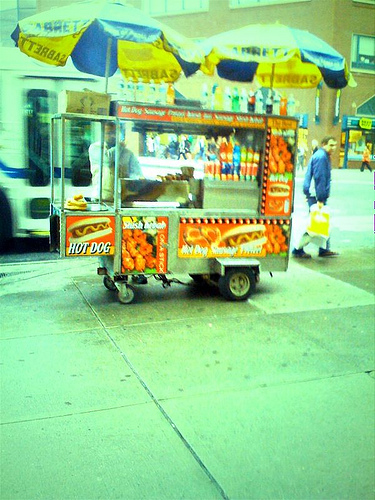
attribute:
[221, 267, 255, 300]
tire — black, small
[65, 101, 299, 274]
hot dog sign — red, yellow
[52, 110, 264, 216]
display — encased in glass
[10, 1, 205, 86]
sabrett umbrella — blue, yellow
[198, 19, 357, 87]
sabrett umbrella — blue, yellow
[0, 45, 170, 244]
commuter bus — moving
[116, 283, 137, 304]
wheel — small, black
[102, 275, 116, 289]
wheel — small, black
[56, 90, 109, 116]
cardboard box — large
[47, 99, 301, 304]
cart — hot dog stand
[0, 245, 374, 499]
sidewalk — gray, wet, gum-stained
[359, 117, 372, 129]
best buy sign — yellow, black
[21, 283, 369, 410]
spots — black, small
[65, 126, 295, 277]
picture — hot dog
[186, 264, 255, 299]
wheels — large, black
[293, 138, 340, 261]
man — walking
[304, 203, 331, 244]
bag — yellow, large, white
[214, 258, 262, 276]
cover — long, silver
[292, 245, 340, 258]
sneakers — black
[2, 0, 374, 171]
building — large, brown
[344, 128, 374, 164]
window — large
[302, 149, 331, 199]
jacket — blue, white